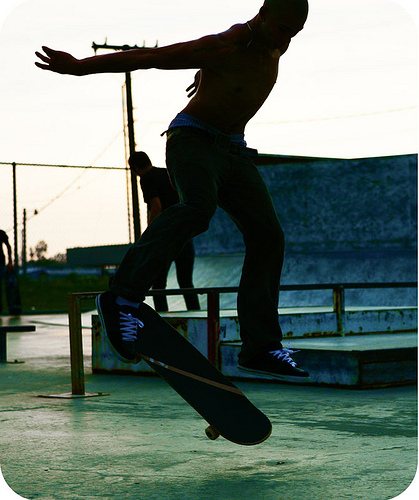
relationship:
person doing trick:
[34, 0, 319, 383] [89, 271, 317, 454]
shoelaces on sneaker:
[116, 306, 145, 347] [92, 288, 150, 365]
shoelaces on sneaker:
[265, 343, 302, 370] [236, 343, 311, 381]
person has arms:
[34, 0, 319, 383] [29, 20, 247, 121]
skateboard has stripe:
[111, 293, 277, 449] [141, 352, 246, 400]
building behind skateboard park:
[58, 238, 139, 269] [0, 153, 416, 499]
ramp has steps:
[87, 242, 419, 313] [89, 297, 417, 388]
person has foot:
[34, 0, 319, 383] [236, 332, 312, 384]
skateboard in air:
[111, 293, 277, 449] [1, 257, 417, 499]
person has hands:
[34, 0, 319, 383] [33, 44, 88, 82]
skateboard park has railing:
[0, 153, 416, 499] [63, 275, 418, 400]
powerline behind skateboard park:
[0, 104, 138, 243] [0, 153, 416, 499]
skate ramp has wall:
[87, 242, 419, 313] [175, 153, 418, 261]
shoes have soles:
[92, 288, 150, 365] [91, 294, 123, 364]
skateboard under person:
[111, 293, 277, 449] [34, 0, 319, 383]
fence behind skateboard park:
[2, 157, 160, 271] [0, 153, 416, 499]